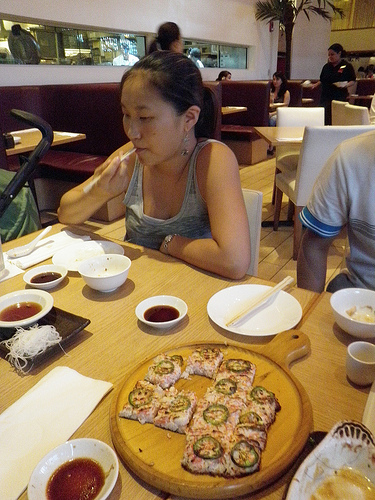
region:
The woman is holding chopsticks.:
[67, 135, 148, 211]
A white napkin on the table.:
[7, 374, 108, 438]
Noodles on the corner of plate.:
[3, 331, 63, 363]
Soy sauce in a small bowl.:
[130, 282, 188, 327]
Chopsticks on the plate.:
[197, 271, 306, 338]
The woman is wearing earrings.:
[173, 128, 185, 159]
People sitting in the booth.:
[224, 56, 300, 128]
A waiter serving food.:
[285, 29, 362, 120]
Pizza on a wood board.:
[131, 348, 301, 474]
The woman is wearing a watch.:
[157, 218, 174, 260]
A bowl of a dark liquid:
[141, 295, 187, 327]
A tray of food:
[133, 341, 292, 476]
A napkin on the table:
[2, 368, 109, 491]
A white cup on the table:
[346, 338, 373, 380]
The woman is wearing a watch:
[160, 234, 178, 246]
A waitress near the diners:
[315, 43, 352, 108]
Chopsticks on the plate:
[223, 277, 293, 327]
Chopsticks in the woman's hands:
[81, 144, 135, 195]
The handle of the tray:
[265, 322, 308, 364]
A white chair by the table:
[274, 107, 318, 166]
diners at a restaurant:
[8, 2, 373, 498]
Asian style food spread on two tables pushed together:
[0, 224, 371, 499]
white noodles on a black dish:
[0, 306, 90, 371]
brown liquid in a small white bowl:
[135, 294, 188, 328]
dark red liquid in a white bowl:
[26, 437, 119, 499]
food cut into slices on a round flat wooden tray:
[112, 327, 315, 497]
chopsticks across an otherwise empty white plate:
[207, 265, 302, 335]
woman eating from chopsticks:
[53, 48, 253, 279]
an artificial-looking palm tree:
[253, 0, 345, 75]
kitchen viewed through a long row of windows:
[0, 12, 249, 69]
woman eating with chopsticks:
[58, 4, 271, 279]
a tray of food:
[102, 336, 316, 469]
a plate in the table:
[199, 267, 308, 339]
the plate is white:
[187, 276, 316, 336]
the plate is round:
[199, 261, 309, 339]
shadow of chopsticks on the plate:
[216, 283, 289, 325]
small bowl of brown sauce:
[119, 281, 189, 331]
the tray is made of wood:
[116, 327, 313, 493]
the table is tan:
[65, 239, 201, 357]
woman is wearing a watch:
[126, 220, 197, 265]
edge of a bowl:
[107, 459, 134, 488]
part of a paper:
[69, 347, 101, 394]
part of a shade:
[129, 479, 149, 495]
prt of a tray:
[304, 443, 329, 485]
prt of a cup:
[345, 366, 358, 392]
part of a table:
[330, 356, 348, 379]